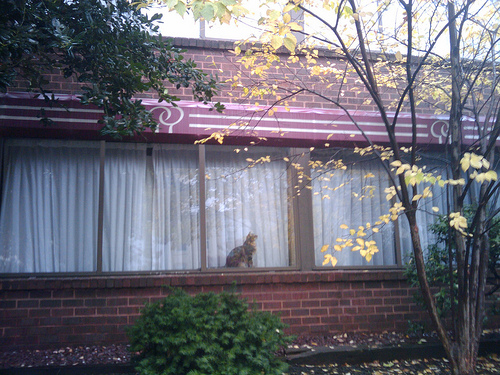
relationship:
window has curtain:
[100, 140, 202, 276] [98, 141, 149, 273]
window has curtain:
[100, 140, 202, 276] [148, 142, 203, 274]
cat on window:
[223, 231, 260, 268] [2, 145, 216, 274]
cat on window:
[223, 231, 260, 268] [9, 139, 498, 267]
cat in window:
[223, 231, 260, 268] [99, 134, 324, 291]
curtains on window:
[6, 161, 445, 258] [9, 139, 498, 267]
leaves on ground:
[411, 360, 423, 367] [0, 330, 499, 374]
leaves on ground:
[381, 360, 393, 368] [0, 330, 499, 374]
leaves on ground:
[368, 360, 380, 366] [0, 330, 499, 374]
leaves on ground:
[389, 365, 402, 373] [0, 330, 499, 374]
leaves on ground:
[423, 367, 433, 374] [0, 330, 499, 374]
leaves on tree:
[387, 158, 436, 185] [190, 5, 495, 372]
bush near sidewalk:
[127, 295, 297, 374] [5, 263, 487, 327]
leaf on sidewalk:
[344, 331, 361, 349] [2, 330, 497, 372]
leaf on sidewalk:
[74, 349, 88, 363] [2, 330, 497, 372]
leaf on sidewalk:
[15, 360, 29, 372] [2, 330, 497, 372]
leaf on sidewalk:
[308, 346, 318, 356] [2, 330, 497, 372]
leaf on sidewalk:
[480, 326, 491, 337] [2, 330, 497, 372]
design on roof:
[147, 105, 182, 132] [0, 92, 497, 142]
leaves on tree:
[238, 12, 328, 90] [5, 7, 212, 146]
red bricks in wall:
[17, 279, 426, 361] [9, 263, 494, 373]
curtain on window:
[152, 145, 289, 270] [0, 138, 291, 273]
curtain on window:
[0, 138, 148, 273] [0, 138, 291, 273]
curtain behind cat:
[101, 145, 289, 273] [216, 219, 276, 271]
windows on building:
[0, 141, 460, 273] [6, 26, 497, 364]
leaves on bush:
[151, 298, 287, 366] [130, 285, 291, 373]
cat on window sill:
[223, 231, 260, 268] [206, 266, 296, 271]